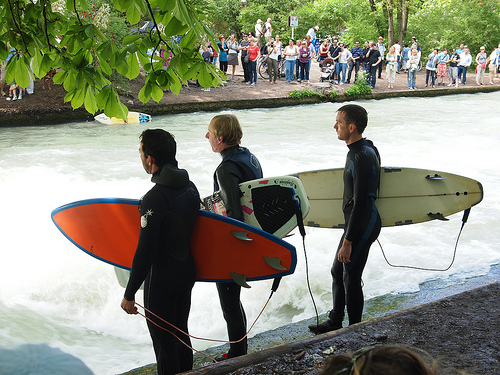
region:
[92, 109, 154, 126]
The surfboard in the water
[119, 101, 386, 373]
The three surfers on the near side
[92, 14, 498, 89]
The spectators across the water way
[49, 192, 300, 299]
The red and blue surf board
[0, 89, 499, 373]
The water way being surfed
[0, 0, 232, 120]
The branches blocking some of the spectators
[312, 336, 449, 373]
The hair of a spectator on the near side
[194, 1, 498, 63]
The trees in the background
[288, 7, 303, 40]
The white sign on the far side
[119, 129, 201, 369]
The surfer holding the red surfboard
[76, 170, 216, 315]
The man has a surfboard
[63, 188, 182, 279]
The man has an orange and blue surfboard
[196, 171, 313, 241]
The other person has a surfboard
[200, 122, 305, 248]
The other person has a white and pink surfboard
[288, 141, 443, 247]
The person has a surfboard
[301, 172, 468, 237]
The person has a white surfboard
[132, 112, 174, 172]
The man has black hair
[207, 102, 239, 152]
The person has blond hair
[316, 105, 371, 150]
The person has grey hair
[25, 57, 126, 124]
The leaves are green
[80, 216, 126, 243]
red surfboard held by man.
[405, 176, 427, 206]
white surfboard held by man.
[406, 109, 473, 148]
rushing water between ledges.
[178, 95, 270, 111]
ledge near rushing water.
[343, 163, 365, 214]
black wetsuit worn by surfer.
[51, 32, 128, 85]
green leaves hanging from tree.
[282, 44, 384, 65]
crowd standing near the water.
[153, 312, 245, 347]
cord attached to surfboard.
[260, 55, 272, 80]
bicycle tire near person.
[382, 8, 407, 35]
tree trunk behind crowd.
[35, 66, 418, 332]
three men in swimwear ready to surf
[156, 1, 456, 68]
people standing on the side of the river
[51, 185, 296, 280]
man holding read surfboard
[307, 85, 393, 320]
man holding white surf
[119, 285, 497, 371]
the side of the river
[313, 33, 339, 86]
man holding stroller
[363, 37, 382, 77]
man with black shirt standing beside the river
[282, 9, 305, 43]
sign near the river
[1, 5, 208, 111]
leaves on the top of the man head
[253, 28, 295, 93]
lady holding a video recorder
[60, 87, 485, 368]
three surfers standing on a ledge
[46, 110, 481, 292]
surfers with boards under their arms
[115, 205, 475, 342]
cords hanging from surfboards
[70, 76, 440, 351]
water rushing through a canal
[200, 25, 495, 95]
people watching from side of canal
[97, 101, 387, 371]
surfers wearing black wetsuits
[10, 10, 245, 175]
branch hanging down near surfers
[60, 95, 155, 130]
surfboard floating along low wall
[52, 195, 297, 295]
red surfboard with grey fins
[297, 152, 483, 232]
white surfboard with line down middle